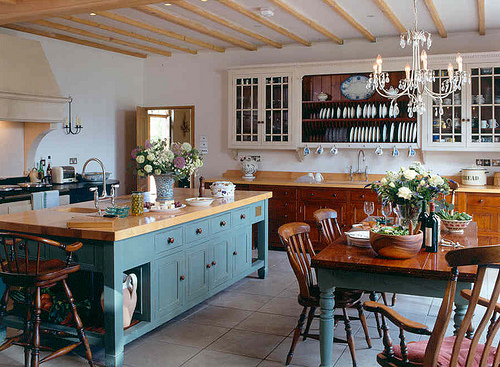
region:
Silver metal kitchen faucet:
[74, 138, 139, 216]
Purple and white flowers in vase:
[125, 123, 210, 216]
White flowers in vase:
[370, 154, 465, 249]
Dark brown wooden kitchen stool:
[1, 219, 98, 365]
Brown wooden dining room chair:
[258, 208, 369, 365]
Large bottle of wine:
[413, 191, 446, 268]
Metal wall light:
[59, 81, 85, 151]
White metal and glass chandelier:
[357, 10, 475, 132]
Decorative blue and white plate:
[337, 68, 374, 106]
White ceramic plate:
[179, 191, 220, 210]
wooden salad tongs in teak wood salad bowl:
[366, 213, 424, 260]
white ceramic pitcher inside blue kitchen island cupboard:
[123, 269, 140, 328]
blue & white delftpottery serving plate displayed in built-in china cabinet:
[337, 73, 378, 100]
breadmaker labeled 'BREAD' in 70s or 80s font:
[456, 162, 491, 187]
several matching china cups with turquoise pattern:
[298, 140, 420, 157]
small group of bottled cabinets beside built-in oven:
[28, 152, 57, 183]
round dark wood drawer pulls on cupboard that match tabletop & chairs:
[165, 210, 248, 285]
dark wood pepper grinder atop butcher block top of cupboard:
[196, 173, 208, 199]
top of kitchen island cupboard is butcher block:
[0, 182, 275, 243]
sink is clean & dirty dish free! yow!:
[322, 146, 392, 186]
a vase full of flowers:
[131, 135, 201, 200]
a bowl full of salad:
[365, 216, 428, 261]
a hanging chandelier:
[362, 0, 472, 115]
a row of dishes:
[303, 105, 421, 118]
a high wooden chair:
[1, 229, 95, 365]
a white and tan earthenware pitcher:
[98, 268, 141, 331]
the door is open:
[130, 96, 194, 190]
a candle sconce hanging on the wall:
[57, 88, 85, 135]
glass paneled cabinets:
[236, 71, 292, 147]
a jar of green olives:
[131, 189, 146, 219]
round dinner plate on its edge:
[348, 124, 354, 143]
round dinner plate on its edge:
[318, 107, 321, 117]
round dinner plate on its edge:
[326, 105, 332, 117]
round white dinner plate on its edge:
[349, 127, 354, 143]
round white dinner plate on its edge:
[366, 124, 372, 140]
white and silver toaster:
[53, 162, 76, 185]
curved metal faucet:
[81, 158, 119, 204]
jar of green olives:
[129, 190, 145, 213]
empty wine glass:
[363, 200, 373, 220]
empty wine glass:
[381, 198, 393, 221]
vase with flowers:
[126, 138, 203, 200]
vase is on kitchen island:
[1, 136, 274, 365]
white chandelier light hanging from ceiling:
[373, 1, 472, 115]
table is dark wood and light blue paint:
[313, 211, 480, 365]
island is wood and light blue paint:
[1, 188, 274, 364]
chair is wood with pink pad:
[362, 234, 499, 364]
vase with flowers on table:
[371, 166, 452, 235]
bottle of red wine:
[423, 201, 441, 255]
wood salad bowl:
[367, 222, 422, 261]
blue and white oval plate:
[341, 76, 376, 102]